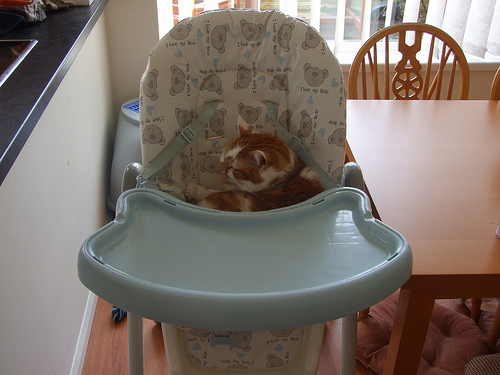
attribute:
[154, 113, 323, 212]
cat — big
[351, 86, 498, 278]
table — smooth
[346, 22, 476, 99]
chair — wood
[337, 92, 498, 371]
table — smooth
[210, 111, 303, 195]
head — turned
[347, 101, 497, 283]
table surface — smooth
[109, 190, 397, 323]
tray — light blue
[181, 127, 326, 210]
bear — big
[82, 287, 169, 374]
floor — smooth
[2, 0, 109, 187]
counter — black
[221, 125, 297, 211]
bear — big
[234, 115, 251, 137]
ear — white, orange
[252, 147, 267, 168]
ear — orange, white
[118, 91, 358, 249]
animal — sitting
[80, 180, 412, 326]
tray — blue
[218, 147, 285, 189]
stripe — white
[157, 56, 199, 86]
slats — white